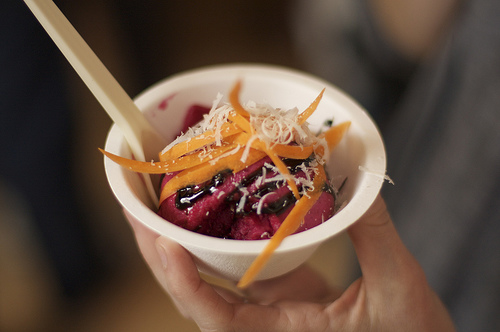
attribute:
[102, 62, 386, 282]
bowl — small, plastic, ivory, rough, white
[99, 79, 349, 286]
carrots — sliced, orange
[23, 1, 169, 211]
utensil — plastic, ivory colored, white, spoon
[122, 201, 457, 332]
hand — creased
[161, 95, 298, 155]
cheese — shredded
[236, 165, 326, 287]
carrot piece — hanging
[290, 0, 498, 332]
person — standing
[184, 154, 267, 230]
strawberries — sliced, red, purple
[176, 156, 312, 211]
jam — dark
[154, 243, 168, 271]
nail — clear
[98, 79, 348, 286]
fruit — orange, purple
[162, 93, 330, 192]
coconut — shredded